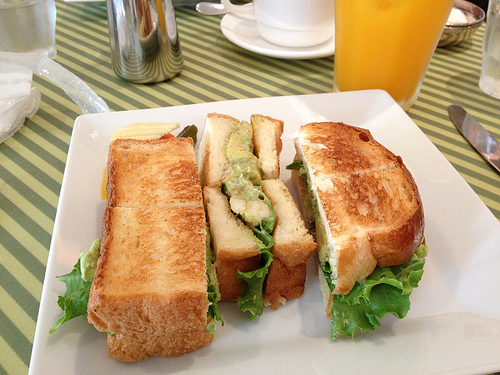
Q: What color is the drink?
A: Yellow.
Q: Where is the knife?
A: On the right.